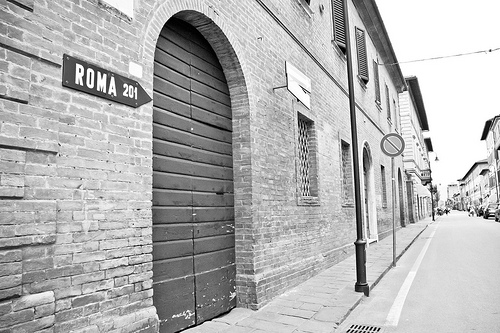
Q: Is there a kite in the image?
A: No, there are no kites.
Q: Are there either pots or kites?
A: No, there are no kites or pots.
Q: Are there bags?
A: No, there are no bags.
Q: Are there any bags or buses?
A: No, there are no bags or buses.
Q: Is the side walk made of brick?
A: Yes, the side walk is made of brick.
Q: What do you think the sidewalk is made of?
A: The sidewalk is made of brick.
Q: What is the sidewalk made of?
A: The sidewalk is made of brick.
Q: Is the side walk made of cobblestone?
A: No, the side walk is made of brick.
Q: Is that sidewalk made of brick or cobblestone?
A: The sidewalk is made of brick.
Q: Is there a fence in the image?
A: No, there are no fences.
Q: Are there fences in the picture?
A: No, there are no fences.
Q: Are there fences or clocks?
A: No, there are no fences or clocks.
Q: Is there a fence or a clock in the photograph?
A: No, there are no fences or clocks.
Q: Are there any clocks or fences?
A: No, there are no fences or clocks.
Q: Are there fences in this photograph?
A: No, there are no fences.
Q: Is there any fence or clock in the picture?
A: No, there are no fences or clocks.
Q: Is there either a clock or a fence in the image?
A: No, there are no fences or clocks.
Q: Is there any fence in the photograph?
A: No, there are no fences.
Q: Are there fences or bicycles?
A: No, there are no fences or bicycles.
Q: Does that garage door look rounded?
A: Yes, the garage door is rounded.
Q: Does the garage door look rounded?
A: Yes, the garage door is rounded.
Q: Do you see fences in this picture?
A: No, there are no fences.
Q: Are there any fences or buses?
A: No, there are no fences or buses.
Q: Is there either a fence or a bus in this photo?
A: No, there are no fences or buses.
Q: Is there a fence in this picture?
A: No, there are no fences.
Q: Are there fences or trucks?
A: No, there are no fences or trucks.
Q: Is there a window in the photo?
A: Yes, there is a window.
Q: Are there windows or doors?
A: Yes, there is a window.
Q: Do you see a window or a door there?
A: Yes, there is a window.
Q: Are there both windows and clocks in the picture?
A: No, there is a window but no clocks.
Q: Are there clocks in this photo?
A: No, there are no clocks.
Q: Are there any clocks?
A: No, there are no clocks.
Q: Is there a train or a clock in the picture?
A: No, there are no clocks or trains.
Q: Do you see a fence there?
A: No, there are no fences.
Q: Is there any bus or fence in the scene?
A: No, there are no fences or buses.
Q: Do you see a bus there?
A: No, there are no buses.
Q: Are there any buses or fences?
A: No, there are no buses or fences.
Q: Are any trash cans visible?
A: No, there are no trash cans.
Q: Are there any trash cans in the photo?
A: No, there are no trash cans.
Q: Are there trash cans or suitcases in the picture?
A: No, there are no trash cans or suitcases.